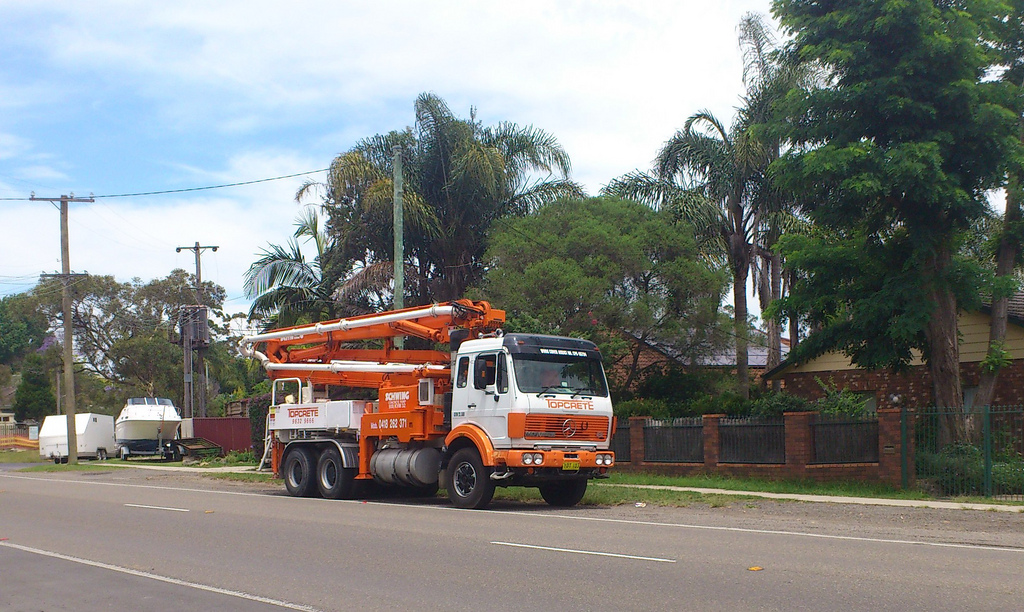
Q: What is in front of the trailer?
A: Large pole.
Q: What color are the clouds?
A: White.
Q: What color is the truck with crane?
A: Orange and white.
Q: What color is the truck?
A: Orange and white.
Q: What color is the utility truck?
A: Orange and white.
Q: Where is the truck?
A: On the street.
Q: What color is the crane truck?
A: Orange and white.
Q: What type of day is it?
A: Sunny and cloudy.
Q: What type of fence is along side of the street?
A: Brick and iron.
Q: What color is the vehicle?
A: Orange.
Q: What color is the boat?
A: White.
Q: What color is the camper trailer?
A: White.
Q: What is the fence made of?
A: Brick.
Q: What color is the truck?
A: White and orange.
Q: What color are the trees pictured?
A: Green.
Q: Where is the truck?
A: On the road.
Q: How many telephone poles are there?
A: 2.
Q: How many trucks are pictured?
A: 1.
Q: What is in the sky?
A: Clouds.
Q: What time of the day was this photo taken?
A: Afternoon or morning.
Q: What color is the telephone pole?
A: Brown.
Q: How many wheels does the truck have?
A: 6.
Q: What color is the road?
A: Grey.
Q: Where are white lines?
A: On the street.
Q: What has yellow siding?
A: House.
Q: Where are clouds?
A: In the sky.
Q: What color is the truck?
A: Orange and white.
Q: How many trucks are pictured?
A: One.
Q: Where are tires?
A: On a truck.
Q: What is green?
A: Trees.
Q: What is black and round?
A: Tires.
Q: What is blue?
A: Sky.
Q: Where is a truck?
A: On the road.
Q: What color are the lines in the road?
A: White.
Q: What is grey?
A: The road.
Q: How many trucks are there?
A: One.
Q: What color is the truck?
A: Orange and white.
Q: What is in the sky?
A: Clouds.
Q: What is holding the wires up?
A: Telephone poles.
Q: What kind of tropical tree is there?
A: Palm.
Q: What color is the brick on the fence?
A: Red.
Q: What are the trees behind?
A: Fence.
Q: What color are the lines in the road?
A: White.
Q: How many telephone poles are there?
A: 5.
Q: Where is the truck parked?
A: Side of the road.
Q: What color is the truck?
A: Orange and white.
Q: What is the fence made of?
A: Brick and iron.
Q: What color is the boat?
A: White.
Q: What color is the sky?
A: Blue.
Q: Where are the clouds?
A: In the sky.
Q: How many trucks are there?
A: 1.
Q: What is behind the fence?
A: Houses.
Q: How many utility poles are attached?
A: Three.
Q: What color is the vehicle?
A: Orange.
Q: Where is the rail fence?
A: In front of the house.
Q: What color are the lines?
A: White.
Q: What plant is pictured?
A: Palm trees.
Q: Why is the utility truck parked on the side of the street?
A: For safety.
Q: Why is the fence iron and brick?
A: For protection.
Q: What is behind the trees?
A: House.